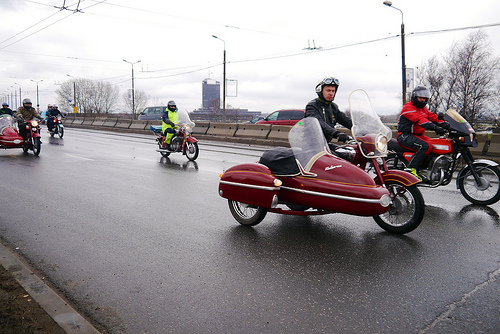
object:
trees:
[55, 79, 120, 117]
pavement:
[0, 112, 500, 334]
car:
[138, 104, 167, 121]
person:
[161, 100, 179, 149]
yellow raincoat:
[162, 109, 180, 134]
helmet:
[315, 78, 339, 92]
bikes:
[0, 111, 41, 156]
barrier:
[56, 110, 288, 148]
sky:
[0, 0, 500, 125]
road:
[0, 124, 499, 334]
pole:
[384, 0, 409, 112]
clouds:
[2, 0, 498, 118]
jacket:
[398, 101, 447, 136]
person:
[45, 104, 52, 115]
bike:
[45, 115, 65, 137]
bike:
[216, 88, 425, 233]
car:
[254, 109, 306, 126]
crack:
[410, 261, 500, 334]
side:
[62, 106, 497, 166]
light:
[378, 0, 405, 22]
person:
[0, 103, 12, 116]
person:
[15, 98, 44, 144]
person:
[49, 104, 63, 133]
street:
[0, 107, 500, 334]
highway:
[0, 112, 500, 334]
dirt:
[0, 272, 63, 334]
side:
[0, 236, 115, 334]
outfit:
[397, 86, 443, 168]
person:
[303, 76, 352, 152]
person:
[398, 87, 450, 179]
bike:
[371, 108, 499, 204]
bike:
[156, 109, 199, 161]